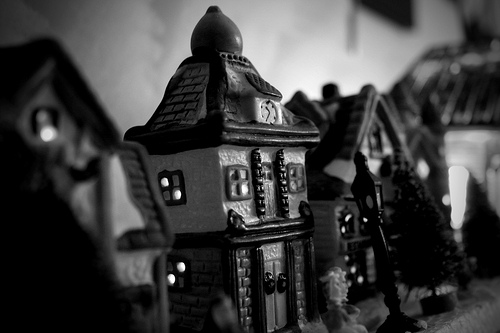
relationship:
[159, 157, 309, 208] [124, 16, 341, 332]
windows on house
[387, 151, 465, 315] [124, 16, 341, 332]
tree next to house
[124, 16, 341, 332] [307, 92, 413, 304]
house next to house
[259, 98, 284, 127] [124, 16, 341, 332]
clock on house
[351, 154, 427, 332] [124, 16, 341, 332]
lamp post in front of house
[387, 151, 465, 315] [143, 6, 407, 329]
tree in between houses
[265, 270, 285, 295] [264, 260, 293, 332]
handles on a door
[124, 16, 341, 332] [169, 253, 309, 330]
house half brick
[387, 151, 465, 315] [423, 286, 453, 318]
tree in planter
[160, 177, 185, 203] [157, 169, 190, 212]
light in window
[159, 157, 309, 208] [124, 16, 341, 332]
windows in house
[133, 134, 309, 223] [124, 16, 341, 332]
top floor of house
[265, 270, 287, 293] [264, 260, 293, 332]
design on door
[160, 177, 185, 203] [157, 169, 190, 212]
lights inside window